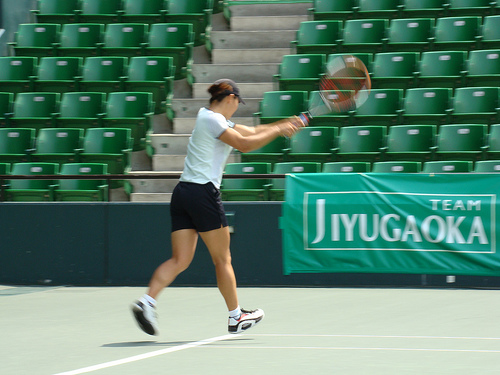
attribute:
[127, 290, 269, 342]
shoes — black, white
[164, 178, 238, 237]
shorts — blue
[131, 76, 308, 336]
woman — head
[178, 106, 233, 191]
shirt — white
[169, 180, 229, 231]
pants — black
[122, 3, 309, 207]
stairs — cement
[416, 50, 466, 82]
seats — empty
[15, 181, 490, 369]
court — green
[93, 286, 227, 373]
lines — white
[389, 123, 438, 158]
chair — bunch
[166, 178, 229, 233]
shorts — black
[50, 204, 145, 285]
padding — wall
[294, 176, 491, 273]
banner — green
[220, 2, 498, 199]
green seats — empty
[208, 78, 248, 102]
cap — black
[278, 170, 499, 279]
banner — green, white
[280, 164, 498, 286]
sign — green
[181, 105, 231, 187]
shirt — light blue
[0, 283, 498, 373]
court — light green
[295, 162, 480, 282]
text — white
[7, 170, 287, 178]
railing — metal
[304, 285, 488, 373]
court — tennis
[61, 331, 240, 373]
lines — white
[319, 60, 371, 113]
racket net — red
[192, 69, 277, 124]
hat — gray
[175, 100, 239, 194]
blouse — white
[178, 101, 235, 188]
shirt — white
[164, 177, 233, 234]
shorts — black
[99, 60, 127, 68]
tag — white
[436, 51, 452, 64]
tag — white